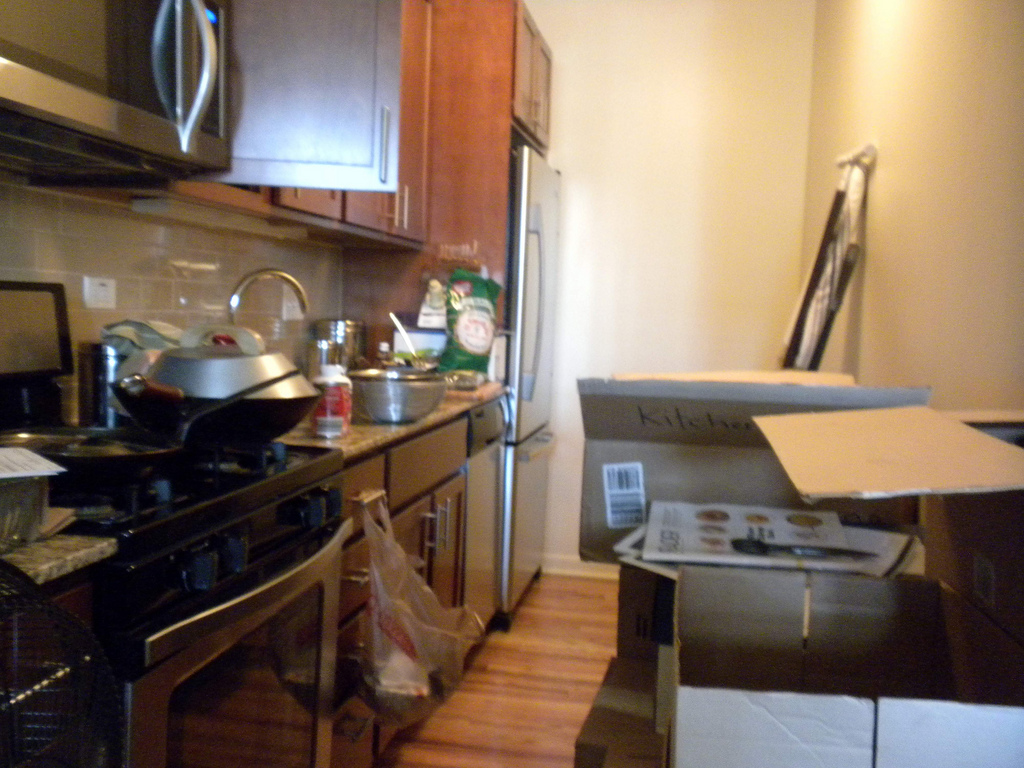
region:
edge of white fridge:
[490, 442, 523, 589]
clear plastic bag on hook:
[330, 481, 487, 726]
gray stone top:
[31, 532, 98, 568]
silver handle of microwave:
[145, 12, 281, 140]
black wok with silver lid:
[91, 293, 354, 467]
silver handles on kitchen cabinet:
[419, 487, 476, 570]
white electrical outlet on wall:
[72, 248, 131, 318]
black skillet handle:
[161, 346, 357, 457]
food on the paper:
[678, 515, 723, 534]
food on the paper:
[699, 530, 725, 547]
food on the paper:
[703, 546, 730, 559]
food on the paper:
[747, 506, 768, 523]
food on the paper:
[794, 511, 817, 525]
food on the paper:
[753, 518, 777, 531]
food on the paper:
[744, 533, 770, 565]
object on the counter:
[422, 296, 479, 372]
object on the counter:
[447, 360, 482, 399]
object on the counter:
[396, 310, 447, 359]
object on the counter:
[321, 363, 439, 436]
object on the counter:
[288, 356, 347, 433]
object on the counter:
[146, 339, 323, 423]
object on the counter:
[65, 318, 133, 427]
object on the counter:
[81, 307, 200, 361]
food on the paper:
[693, 508, 728, 521]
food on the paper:
[725, 506, 776, 530]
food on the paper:
[770, 505, 816, 522]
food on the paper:
[693, 525, 732, 541]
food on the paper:
[734, 522, 774, 539]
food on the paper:
[808, 527, 812, 531]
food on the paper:
[740, 531, 766, 550]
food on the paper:
[813, 540, 830, 567]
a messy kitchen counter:
[0, 233, 501, 585]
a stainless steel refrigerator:
[332, 139, 568, 629]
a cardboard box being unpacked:
[566, 366, 1022, 567]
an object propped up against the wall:
[778, 142, 877, 365]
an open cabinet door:
[215, 0, 397, 193]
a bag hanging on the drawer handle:
[346, 493, 493, 702]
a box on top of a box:
[615, 505, 926, 658]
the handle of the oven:
[130, 514, 358, 658]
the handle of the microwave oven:
[177, 0, 217, 154]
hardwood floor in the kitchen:
[386, 565, 678, 763]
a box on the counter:
[617, 320, 874, 618]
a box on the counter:
[634, 613, 771, 750]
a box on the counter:
[845, 373, 1002, 583]